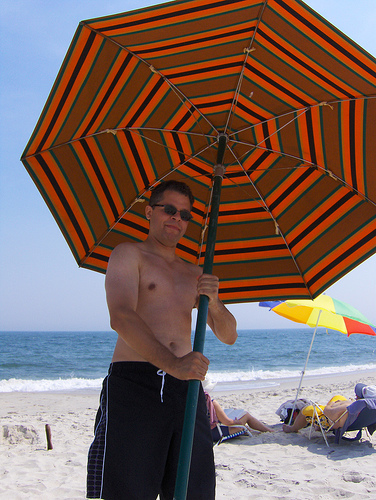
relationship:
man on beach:
[80, 157, 258, 499] [2, 365, 373, 500]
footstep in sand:
[7, 421, 40, 450] [6, 374, 374, 499]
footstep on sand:
[7, 421, 40, 450] [6, 374, 374, 499]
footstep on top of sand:
[7, 421, 40, 450] [6, 374, 374, 499]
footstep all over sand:
[7, 421, 40, 450] [6, 374, 374, 499]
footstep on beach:
[7, 421, 40, 450] [2, 365, 373, 500]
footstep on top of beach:
[7, 421, 40, 450] [2, 365, 373, 500]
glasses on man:
[145, 199, 194, 224] [80, 157, 258, 499]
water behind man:
[2, 331, 374, 374] [80, 157, 258, 499]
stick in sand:
[40, 420, 63, 459] [6, 374, 374, 499]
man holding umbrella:
[80, 157, 258, 499] [12, 3, 375, 300]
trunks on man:
[84, 359, 227, 499] [80, 157, 258, 499]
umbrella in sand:
[12, 3, 375, 300] [6, 374, 374, 499]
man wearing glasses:
[80, 157, 258, 499] [145, 199, 194, 224]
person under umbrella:
[276, 373, 373, 441] [254, 283, 375, 347]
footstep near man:
[7, 421, 40, 450] [80, 157, 258, 499]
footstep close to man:
[7, 421, 40, 450] [80, 157, 258, 499]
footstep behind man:
[7, 421, 40, 450] [80, 157, 258, 499]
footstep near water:
[7, 421, 40, 450] [2, 331, 374, 374]